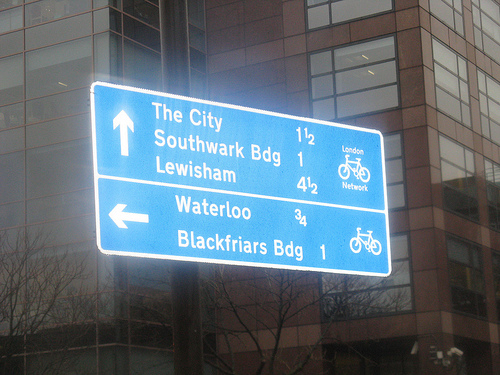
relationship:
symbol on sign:
[349, 227, 382, 255] [87, 80, 395, 279]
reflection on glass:
[5, 236, 86, 350] [3, 6, 198, 340]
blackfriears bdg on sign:
[178, 230, 304, 262] [87, 80, 395, 279]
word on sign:
[151, 152, 238, 183] [76, 84, 390, 268]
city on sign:
[152, 101, 223, 132] [95, 176, 387, 280]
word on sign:
[187, 105, 225, 134] [95, 176, 387, 280]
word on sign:
[148, 149, 249, 191] [95, 176, 387, 280]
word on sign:
[187, 105, 225, 134] [87, 80, 395, 279]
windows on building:
[303, 34, 399, 121] [3, 7, 496, 367]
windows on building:
[429, 34, 471, 128] [3, 7, 496, 367]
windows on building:
[476, 68, 498, 144] [3, 7, 496, 367]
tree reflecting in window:
[144, 259, 414, 374] [333, 45, 397, 61]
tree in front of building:
[144, 259, 414, 374] [3, 7, 496, 367]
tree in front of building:
[3, 225, 120, 374] [3, 7, 496, 367]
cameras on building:
[405, 331, 490, 365] [229, 33, 489, 327]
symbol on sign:
[346, 223, 382, 256] [87, 80, 395, 279]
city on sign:
[151, 99, 226, 134] [87, 80, 395, 279]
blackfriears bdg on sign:
[178, 227, 308, 263] [87, 80, 395, 279]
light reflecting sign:
[108, 181, 131, 211] [52, 62, 403, 295]